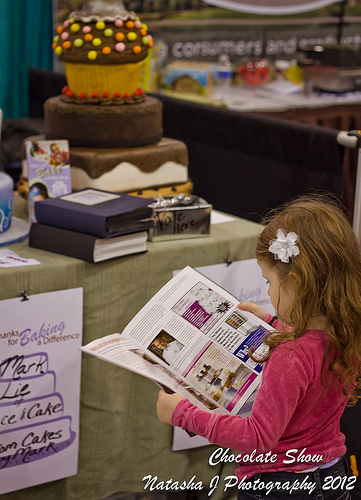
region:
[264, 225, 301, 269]
A flower in the girl hair.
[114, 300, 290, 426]
The girl is reading a magazine.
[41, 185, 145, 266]
Books on the table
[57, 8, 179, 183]
A huge cake on the table.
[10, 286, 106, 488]
A purple sign on the side of the table.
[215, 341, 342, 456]
The girl is wearing a pink shirt.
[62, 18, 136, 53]
Sprinkles on the cupcake.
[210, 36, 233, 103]
A water bottle sitting on the table.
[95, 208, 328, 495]
girl is reading the brochures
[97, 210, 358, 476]
girl is reading the brochures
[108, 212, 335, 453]
girl is reading the brochures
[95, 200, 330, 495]
girl is reading the brochures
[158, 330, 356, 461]
the shirt is pink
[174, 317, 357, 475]
the shirt is pink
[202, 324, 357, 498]
the shirt is pink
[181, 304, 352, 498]
the shirt is pink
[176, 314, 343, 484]
the shirt is pink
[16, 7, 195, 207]
a really big stack of chocolate-frosted pastries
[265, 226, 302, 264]
this little girl is wearing a flower hairclip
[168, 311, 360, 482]
this young lady is wearing a pink velour top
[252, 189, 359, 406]
this young lady has long red hair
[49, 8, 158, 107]
the giant cupcake has giant sprinkles on top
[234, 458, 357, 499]
the young lady is wearing jeans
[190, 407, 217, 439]
the young lady has a heart design on her sleeve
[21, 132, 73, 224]
a colorful brochure is displayed on the table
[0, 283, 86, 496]
a hand-lettered sign on the front of the table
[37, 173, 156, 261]
two photo albums on table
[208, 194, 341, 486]
little girl reading a magazine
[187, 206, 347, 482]
little girl wearing a pink shirt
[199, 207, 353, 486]
little girl with red hair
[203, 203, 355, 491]
little girl with flower in her hair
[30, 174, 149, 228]
blue photo album on top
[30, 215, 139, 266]
black photo album on bottom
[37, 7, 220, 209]
four tier cake with cupcake on top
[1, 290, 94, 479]
sign attached to table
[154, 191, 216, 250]
silver box with black letters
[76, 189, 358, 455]
Little girl holding a magazine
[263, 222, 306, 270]
White flower in girl's hair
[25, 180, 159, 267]
Two books on top of each other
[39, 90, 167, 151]
A round chocolate cake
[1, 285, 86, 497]
A sign attached to a table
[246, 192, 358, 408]
The brown hair is long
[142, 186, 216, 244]
A silver gift box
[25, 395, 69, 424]
The word "Cake" on a sign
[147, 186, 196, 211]
A silver bow on a box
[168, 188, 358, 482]
Girl is wearing a pink sweater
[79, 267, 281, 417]
a large book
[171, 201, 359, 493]
a girl in a pink shirt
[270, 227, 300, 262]
a white flower in the girls hair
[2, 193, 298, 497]
a green table cloth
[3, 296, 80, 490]
a sign on the table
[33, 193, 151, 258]
books on top of the table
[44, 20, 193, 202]
a large cake on a table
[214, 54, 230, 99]
a water bottle on the table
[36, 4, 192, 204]
a large brown cake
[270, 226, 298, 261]
flower in girls hair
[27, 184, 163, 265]
books laying on table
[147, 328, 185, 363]
picture of man in magazine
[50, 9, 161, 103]
giant yellow cupcake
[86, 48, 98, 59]
yellow ball on cupcake